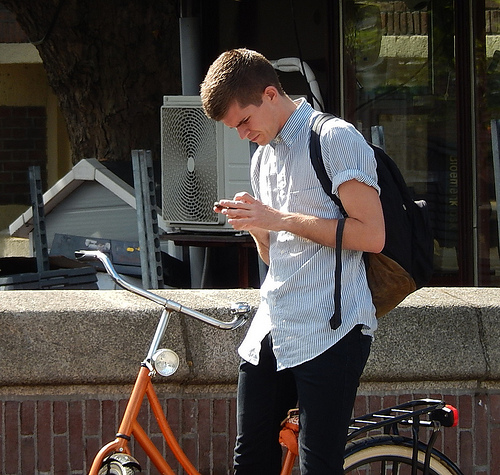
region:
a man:
[174, 54, 397, 374]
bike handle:
[117, 255, 212, 312]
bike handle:
[100, 240, 244, 354]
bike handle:
[111, 262, 293, 412]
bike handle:
[115, 283, 211, 349]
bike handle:
[125, 274, 256, 372]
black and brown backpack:
[343, 122, 450, 341]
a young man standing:
[197, 46, 400, 473]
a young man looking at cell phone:
[197, 43, 384, 471]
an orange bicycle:
[60, 243, 479, 473]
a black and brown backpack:
[305, 110, 437, 315]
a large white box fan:
[158, 93, 242, 231]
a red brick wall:
[6, 396, 498, 473]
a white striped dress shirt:
[229, 107, 377, 374]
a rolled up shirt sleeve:
[320, 119, 387, 198]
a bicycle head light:
[149, 348, 179, 380]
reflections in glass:
[340, 6, 495, 283]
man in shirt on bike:
[158, 38, 423, 472]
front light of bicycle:
[140, 347, 185, 379]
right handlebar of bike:
[57, 239, 164, 314]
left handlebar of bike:
[208, 288, 248, 346]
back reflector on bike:
[428, 395, 460, 440]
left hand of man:
[219, 190, 270, 230]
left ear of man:
[258, 82, 283, 107]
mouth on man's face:
[243, 134, 266, 145]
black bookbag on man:
[333, 142, 438, 313]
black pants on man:
[241, 327, 363, 474]